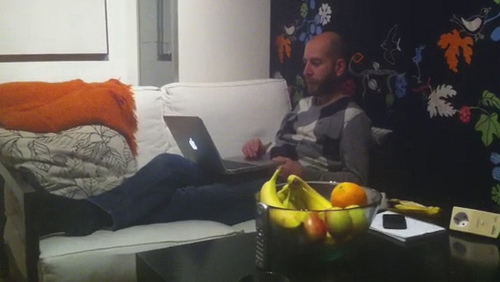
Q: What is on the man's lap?
A: Laptop.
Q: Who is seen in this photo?
A: A man.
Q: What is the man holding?
A: A laptop.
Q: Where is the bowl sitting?
A: On a table.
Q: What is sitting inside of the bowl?
A: Fruit.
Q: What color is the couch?
A: White.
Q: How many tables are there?
A: One.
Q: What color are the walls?
A: White.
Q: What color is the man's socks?
A: Black.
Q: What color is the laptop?
A: Gray.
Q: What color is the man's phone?
A: Black.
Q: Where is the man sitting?
A: Couch.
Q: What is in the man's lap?
A: Laptop.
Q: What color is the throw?
A: Orange.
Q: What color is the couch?
A: White.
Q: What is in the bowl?
A: Fruit.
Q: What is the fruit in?
A: Bowl.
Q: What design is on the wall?
A: Floral.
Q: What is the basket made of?
A: Glass.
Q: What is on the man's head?
A: Nothing.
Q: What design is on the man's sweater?
A: Argyle.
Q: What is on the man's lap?
A: Computer.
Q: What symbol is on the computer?
A: Apple.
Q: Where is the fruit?
A: In a bowl on the table.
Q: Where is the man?
A: On the couch.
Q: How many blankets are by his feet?
A: Two.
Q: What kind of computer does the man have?
A: Apple.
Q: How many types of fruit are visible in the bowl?
A: Three.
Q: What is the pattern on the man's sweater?
A: Argyle.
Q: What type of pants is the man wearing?
A: Blue jeans.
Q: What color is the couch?
A: White.